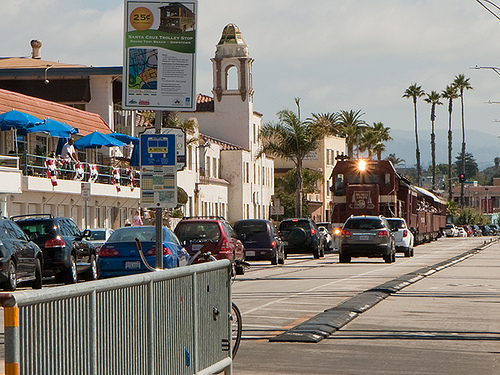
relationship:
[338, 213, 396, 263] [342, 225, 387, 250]
car has back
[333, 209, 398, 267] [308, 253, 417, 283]
car on street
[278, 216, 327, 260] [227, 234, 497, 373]
car on street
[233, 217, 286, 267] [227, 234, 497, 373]
car on street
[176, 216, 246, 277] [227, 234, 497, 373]
car on street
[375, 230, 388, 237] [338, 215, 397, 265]
light on car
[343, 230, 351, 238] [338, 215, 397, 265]
light on car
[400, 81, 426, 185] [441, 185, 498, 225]
palm trees near building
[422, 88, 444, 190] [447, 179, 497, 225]
palm trees near building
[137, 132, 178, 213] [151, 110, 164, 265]
bus top on pole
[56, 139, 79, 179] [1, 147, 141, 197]
people on balcony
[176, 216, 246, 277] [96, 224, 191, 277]
car between car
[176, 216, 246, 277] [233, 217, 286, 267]
car between car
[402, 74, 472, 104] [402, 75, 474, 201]
leaves on palm trees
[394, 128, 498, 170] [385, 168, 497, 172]
mountains on horizon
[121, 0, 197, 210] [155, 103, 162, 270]
signs on pole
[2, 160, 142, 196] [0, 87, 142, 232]
balcony on building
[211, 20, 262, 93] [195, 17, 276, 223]
dome on building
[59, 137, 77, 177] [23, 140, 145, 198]
man on balcony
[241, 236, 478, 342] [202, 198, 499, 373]
lines on road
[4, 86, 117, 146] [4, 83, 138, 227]
roof of building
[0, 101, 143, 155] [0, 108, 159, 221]
umbrellas on balcony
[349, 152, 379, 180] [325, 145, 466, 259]
light on train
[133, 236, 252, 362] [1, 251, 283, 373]
bicycle near barrier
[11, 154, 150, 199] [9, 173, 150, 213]
banners from balcony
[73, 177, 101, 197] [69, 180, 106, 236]
sign on pole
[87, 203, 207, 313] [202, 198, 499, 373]
car on road